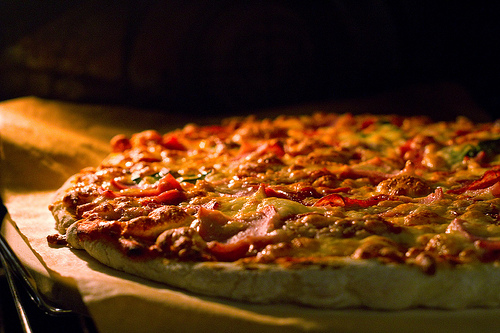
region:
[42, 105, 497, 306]
Pizza on the cloth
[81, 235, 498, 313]
Crust on the pizza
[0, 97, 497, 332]
yellow covering on the table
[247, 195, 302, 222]
melted cheese on the pizza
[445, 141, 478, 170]
bell pepper on the pizza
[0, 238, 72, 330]
metal bars under the surface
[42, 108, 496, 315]
Circle shape on the pizza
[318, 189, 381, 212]
pepperoni on the pizza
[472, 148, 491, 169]
piece of brown sausage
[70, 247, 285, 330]
Shadow from the pizza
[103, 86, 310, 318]
a pizza on a table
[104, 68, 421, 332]
a cooked pizza on a table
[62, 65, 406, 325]
a pizza with cheese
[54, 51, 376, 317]
chees on a baked pizza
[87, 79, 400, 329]
cheese on a pizza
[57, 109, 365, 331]
a pizza that has cheese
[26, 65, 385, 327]
a table with a pizza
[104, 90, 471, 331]
food on a table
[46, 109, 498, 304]
pizza with multiple toppings and thin crust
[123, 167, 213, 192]
green vegetable on pizza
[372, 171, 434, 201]
bubble on the cheese on a pizza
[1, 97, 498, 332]
brown paper with a pizza on top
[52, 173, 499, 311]
crust of a pizza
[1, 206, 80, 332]
partially obscured silverware next to brown paper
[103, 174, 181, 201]
cooked meat on a pizza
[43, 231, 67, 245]
crumb of a pizza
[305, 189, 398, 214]
curled piece of meat on a pizza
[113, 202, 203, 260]
mass of cheese bubbles on a pizza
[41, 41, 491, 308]
Pizza displayed on a table.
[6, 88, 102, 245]
Wax paper under the pizza.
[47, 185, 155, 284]
The crust of a pizza.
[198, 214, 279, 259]
Ham on top of a pizza.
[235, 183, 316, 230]
Bubbling cheese on the pizza.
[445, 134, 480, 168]
Green vegetables on the pizza.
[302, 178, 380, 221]
Pepperoni on a pizza.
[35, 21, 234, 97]
Dark brick wall in the back.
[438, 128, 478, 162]
Peppers on the pizza.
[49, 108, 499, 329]
pizza on brown paper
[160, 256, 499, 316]
tan dough of pizza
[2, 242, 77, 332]
metal rack under pizza paper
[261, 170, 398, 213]
meat on top of pizza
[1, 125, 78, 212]
shadow on brown pizza paper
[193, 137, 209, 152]
light reflecting on surface of pizza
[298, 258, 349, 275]
brown marks on crust of pizza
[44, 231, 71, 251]
cheese crumb on brown pizza paper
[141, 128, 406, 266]
toppings on the pizza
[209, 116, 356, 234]
a pizza with melted cheese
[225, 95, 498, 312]
a baked pizza with cheese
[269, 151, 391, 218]
cheese with toppings on it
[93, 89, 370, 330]
a pizza on the plate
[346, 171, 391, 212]
meat on top of the pizza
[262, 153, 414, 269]
yellow cheese on the pizza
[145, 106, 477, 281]
meat baked on a pizza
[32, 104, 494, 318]
this is a pizza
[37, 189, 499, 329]
this is the crust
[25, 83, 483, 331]
the pizza is on a sheet of paper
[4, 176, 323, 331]
a brown piece of paper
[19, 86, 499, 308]
there is a lot of meat on the pizza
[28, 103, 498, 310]
the pizza is covered in many toppings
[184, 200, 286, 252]
this is canadian bacon